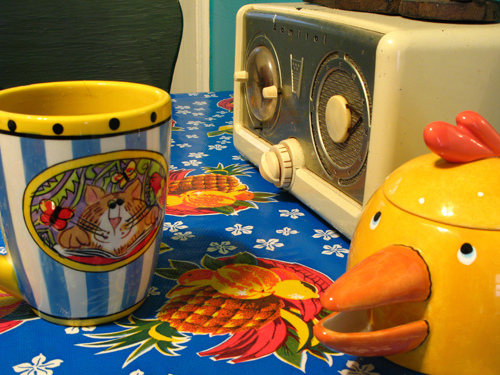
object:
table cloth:
[173, 90, 257, 371]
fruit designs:
[169, 162, 275, 220]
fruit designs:
[127, 251, 350, 363]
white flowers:
[249, 236, 284, 252]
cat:
[63, 181, 160, 253]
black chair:
[1, 0, 184, 76]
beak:
[318, 247, 428, 357]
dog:
[62, 182, 153, 259]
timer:
[226, 4, 499, 233]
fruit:
[174, 172, 241, 192]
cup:
[2, 70, 177, 332]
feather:
[421, 109, 498, 164]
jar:
[307, 108, 497, 373]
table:
[0, 92, 243, 375]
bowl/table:
[316, 111, 499, 372]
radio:
[214, 4, 500, 191]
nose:
[317, 245, 430, 355]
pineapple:
[158, 255, 319, 349]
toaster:
[232, 0, 500, 231]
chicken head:
[310, 107, 499, 369]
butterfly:
[39, 199, 74, 230]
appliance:
[233, 2, 500, 229]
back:
[2, 0, 169, 76]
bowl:
[278, 115, 498, 333]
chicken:
[310, 127, 500, 375]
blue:
[46, 263, 68, 315]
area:
[0, 0, 498, 374]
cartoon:
[0, 84, 178, 324]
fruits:
[154, 288, 282, 332]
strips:
[3, 138, 71, 162]